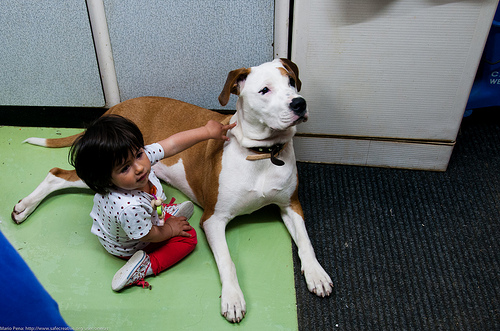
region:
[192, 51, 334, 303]
brown and white dog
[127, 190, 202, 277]
red pants worn by child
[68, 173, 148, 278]
spotted shirt worn by child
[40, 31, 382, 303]
child petting a dog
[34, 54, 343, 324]
a toddler petting a dog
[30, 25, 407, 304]
a toddler touching a dog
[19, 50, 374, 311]
a large brown and white dog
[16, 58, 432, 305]
a large Pitt Bull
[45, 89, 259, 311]
child with dark hair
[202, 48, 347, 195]
dog wearing a collar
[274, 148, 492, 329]
a black grooved rug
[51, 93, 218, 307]
child wearing red pants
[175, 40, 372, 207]
dog looking at someone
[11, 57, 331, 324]
toddler and dog on floor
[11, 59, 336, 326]
brown and white reclined dog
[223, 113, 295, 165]
collar on dog's neck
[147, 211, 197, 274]
red pants on folded leg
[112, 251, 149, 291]
bottom of child's shoe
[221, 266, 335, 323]
white paws with trimmed nails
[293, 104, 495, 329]
gray ribbed rug on floor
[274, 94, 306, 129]
black nose on white snout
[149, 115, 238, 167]
child's finger on fur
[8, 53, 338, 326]
girl and a dog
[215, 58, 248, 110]
an ear of the dog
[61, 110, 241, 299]
a girl wearing red pants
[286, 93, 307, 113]
a nose of the dog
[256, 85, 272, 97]
an eye of the dog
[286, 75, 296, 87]
an eye of the dog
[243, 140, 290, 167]
a collar of the dog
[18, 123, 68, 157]
a tail of the dog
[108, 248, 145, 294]
sole of the shoe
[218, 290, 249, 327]
a paw of the dog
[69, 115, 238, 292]
the girl is young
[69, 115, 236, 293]
the girl is a child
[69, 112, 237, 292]
the girl is sitting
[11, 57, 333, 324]
the dog sitting next to the girl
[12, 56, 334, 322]
the dog is lying down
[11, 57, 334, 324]
the brown and white dog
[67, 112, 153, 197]
the full head of hair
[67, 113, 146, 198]
the hair is dark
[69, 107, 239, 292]
the red and white clothes on the child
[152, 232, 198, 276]
the pants are red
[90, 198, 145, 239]
design on the shirt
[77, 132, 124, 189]
the hair is black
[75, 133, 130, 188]
the hair is cut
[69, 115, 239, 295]
Toddler with a polka dot shirt and red pants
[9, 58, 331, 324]
brown and white dog lying on a floor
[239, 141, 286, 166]
brown collar on a dog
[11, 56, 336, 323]
toddler and dog on the floor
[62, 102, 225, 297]
A person is sitting down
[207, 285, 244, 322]
A paw of an animal.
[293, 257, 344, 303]
A paw of an animal.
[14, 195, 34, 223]
A paw of an animal.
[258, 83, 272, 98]
An eye on a face.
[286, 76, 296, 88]
An eye on a face.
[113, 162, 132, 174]
An eye on a face.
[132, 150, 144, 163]
An eye on a face.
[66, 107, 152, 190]
A head on a body.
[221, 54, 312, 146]
A head on a body.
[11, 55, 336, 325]
Little girl sitting next to a big dog